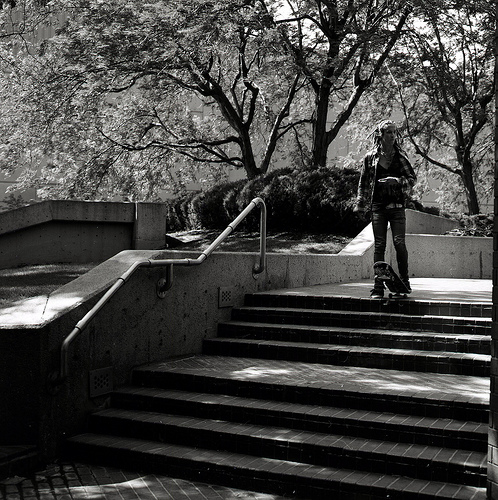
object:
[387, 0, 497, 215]
tree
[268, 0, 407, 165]
tree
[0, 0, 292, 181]
tree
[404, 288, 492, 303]
shadows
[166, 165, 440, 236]
bushes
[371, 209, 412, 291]
dark pants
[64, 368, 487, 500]
stairs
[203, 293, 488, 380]
stairs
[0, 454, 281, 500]
floor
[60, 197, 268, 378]
rail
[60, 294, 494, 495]
side stairs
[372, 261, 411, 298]
skateboard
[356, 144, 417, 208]
shirt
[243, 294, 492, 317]
border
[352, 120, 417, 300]
boy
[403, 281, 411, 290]
feet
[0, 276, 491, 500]
ground